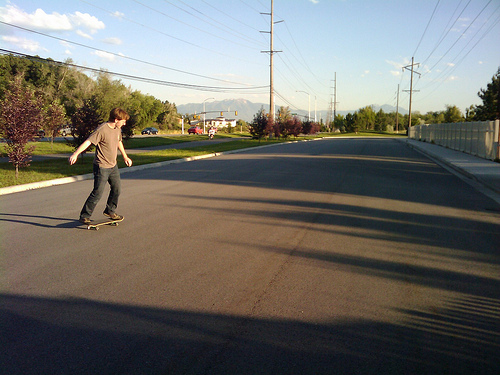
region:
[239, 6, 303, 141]
wooden power pole with wires attached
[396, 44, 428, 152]
wooden power pole with wires attached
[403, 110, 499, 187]
wooden fence along sidewalk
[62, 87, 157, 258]
man skate board down street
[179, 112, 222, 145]
red car at a distance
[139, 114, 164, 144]
black car on highway at a distance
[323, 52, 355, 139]
wooden power pole with wires attached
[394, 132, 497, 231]
cement sidewalk along street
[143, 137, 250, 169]
cement curb along street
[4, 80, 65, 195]
tree with purple leaves on side of street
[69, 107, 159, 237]
Boy riding skateboard.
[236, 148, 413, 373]
The road is smooth and empty.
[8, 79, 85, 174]
Trees on the other side of road.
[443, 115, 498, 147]
A gate is by the sidewalk.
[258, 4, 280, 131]
The electrical poles are tall.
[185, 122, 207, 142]
Red trunk driving on the street.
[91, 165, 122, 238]
The boy is wearing black pants.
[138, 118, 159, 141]
A blue car is driving down the street.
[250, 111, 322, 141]
The trees leaves look like fall.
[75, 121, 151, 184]
The boy arm are spread apart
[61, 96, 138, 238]
Boy skates on road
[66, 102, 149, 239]
Boy has extended arms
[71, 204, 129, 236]
Black skater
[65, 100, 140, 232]
Boy wears brown shirt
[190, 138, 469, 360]
Shadows cast on road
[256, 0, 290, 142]
Electrical pole on left side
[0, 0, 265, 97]
Electrical wires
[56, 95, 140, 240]
Boy stand with open legs on skateboard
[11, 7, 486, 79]
Blue sky with some white clouds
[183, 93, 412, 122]
Mountains on the background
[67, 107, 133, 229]
a young man on a skateboard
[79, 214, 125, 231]
a skateboard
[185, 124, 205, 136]
a red truck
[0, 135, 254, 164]
a sidewalk behind the boy on the skateboard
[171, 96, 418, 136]
mountains can be seen in the distance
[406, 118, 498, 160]
a fence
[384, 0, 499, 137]
power lines can be seen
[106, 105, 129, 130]
a young man with brown hair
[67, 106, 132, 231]
a young man with brown hair wearing a brown shirt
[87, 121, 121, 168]
a brown shirt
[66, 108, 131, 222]
a young man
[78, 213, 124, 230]
a wooden skateboard on the street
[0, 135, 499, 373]
an empty, paved street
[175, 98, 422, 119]
mountains in the distance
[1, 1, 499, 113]
a partly cloudy sky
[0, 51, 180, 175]
trees behind the skater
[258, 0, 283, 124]
a wooden telephone pole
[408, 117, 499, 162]
a fence along the road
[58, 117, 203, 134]
cars behind the skater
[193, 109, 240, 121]
hanging traffic signals